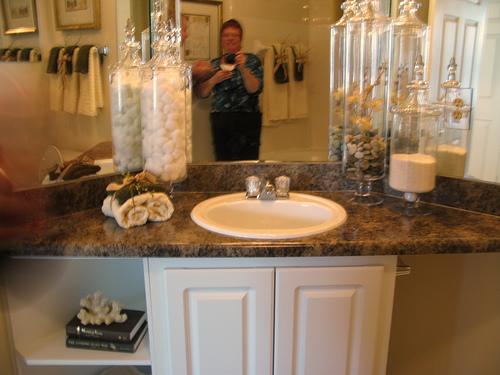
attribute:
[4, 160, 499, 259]
counter — marble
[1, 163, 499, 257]
countertop — brown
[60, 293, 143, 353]
books — stack 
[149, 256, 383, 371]
doors — white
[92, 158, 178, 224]
towels — folded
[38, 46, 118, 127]
towels — hanging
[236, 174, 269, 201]
knobs — silver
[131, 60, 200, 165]
ball — piled, cotton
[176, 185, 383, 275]
sink — white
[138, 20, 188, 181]
jar — glass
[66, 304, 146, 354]
books — black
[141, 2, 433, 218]
jars — three, tall, glass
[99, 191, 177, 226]
towel — rolled up, white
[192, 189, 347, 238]
bathroom sink — white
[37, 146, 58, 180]
seat — up